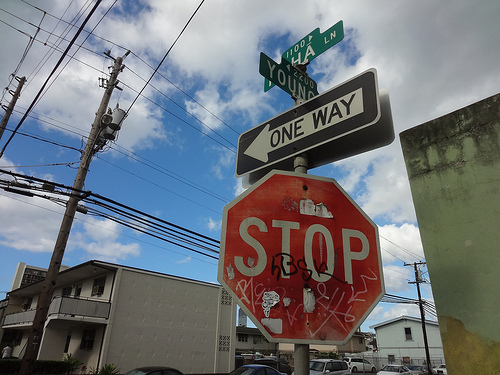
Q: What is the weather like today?
A: It is cloudy.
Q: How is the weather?
A: It is cloudy.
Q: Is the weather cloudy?
A: Yes, it is cloudy.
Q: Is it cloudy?
A: Yes, it is cloudy.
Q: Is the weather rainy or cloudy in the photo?
A: It is cloudy.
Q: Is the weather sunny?
A: No, it is cloudy.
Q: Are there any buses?
A: No, there are no buses.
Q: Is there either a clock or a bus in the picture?
A: No, there are no buses or clocks.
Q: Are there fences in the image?
A: Yes, there is a fence.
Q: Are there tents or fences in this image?
A: Yes, there is a fence.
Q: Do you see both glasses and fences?
A: No, there is a fence but no glasses.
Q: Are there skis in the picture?
A: No, there are no skis.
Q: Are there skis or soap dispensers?
A: No, there are no skis or soap dispensers.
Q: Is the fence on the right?
A: Yes, the fence is on the right of the image.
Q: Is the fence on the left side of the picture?
A: No, the fence is on the right of the image.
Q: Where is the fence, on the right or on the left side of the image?
A: The fence is on the right of the image.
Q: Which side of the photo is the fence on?
A: The fence is on the right of the image.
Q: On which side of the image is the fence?
A: The fence is on the right of the image.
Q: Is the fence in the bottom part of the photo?
A: Yes, the fence is in the bottom of the image.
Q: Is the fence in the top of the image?
A: No, the fence is in the bottom of the image.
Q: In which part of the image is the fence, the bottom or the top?
A: The fence is in the bottom of the image.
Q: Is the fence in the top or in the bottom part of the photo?
A: The fence is in the bottom of the image.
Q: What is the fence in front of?
A: The fence is in front of the building.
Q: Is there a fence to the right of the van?
A: Yes, there is a fence to the right of the van.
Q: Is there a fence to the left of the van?
A: No, the fence is to the right of the van.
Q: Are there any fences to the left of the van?
A: No, the fence is to the right of the van.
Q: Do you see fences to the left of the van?
A: No, the fence is to the right of the van.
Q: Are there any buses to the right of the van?
A: No, there is a fence to the right of the van.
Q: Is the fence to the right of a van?
A: Yes, the fence is to the right of a van.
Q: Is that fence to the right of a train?
A: No, the fence is to the right of a van.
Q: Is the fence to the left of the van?
A: No, the fence is to the right of the van.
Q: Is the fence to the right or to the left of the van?
A: The fence is to the right of the van.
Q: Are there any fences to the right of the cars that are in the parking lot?
A: Yes, there is a fence to the right of the cars.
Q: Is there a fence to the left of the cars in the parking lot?
A: No, the fence is to the right of the cars.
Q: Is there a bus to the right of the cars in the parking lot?
A: No, there is a fence to the right of the cars.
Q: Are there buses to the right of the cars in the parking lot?
A: No, there is a fence to the right of the cars.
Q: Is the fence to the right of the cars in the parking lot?
A: Yes, the fence is to the right of the cars.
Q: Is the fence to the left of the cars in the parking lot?
A: No, the fence is to the right of the cars.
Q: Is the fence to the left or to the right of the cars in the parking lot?
A: The fence is to the right of the cars.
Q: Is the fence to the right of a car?
A: Yes, the fence is to the right of a car.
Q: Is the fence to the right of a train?
A: No, the fence is to the right of a car.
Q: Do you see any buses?
A: No, there are no buses.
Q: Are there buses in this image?
A: No, there are no buses.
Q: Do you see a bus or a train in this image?
A: No, there are no buses or trains.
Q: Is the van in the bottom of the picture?
A: Yes, the van is in the bottom of the image.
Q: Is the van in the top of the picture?
A: No, the van is in the bottom of the image.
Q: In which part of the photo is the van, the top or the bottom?
A: The van is in the bottom of the image.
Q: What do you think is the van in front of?
A: The van is in front of the building.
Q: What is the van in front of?
A: The van is in front of the building.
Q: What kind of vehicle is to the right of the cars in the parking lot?
A: The vehicle is a van.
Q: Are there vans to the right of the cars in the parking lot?
A: Yes, there is a van to the right of the cars.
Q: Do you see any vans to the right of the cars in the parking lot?
A: Yes, there is a van to the right of the cars.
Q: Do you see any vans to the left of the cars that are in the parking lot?
A: No, the van is to the right of the cars.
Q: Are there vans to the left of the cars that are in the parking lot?
A: No, the van is to the right of the cars.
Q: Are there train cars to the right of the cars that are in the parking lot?
A: No, there is a van to the right of the cars.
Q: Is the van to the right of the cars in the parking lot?
A: Yes, the van is to the right of the cars.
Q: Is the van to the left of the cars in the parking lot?
A: No, the van is to the right of the cars.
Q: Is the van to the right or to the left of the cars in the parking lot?
A: The van is to the right of the cars.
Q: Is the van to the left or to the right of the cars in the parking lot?
A: The van is to the right of the cars.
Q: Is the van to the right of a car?
A: Yes, the van is to the right of a car.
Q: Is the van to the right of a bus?
A: No, the van is to the right of a car.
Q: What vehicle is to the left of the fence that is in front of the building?
A: The vehicle is a van.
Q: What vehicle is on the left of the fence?
A: The vehicle is a van.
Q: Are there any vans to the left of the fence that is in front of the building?
A: Yes, there is a van to the left of the fence.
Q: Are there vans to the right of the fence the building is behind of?
A: No, the van is to the left of the fence.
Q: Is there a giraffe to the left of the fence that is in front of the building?
A: No, there is a van to the left of the fence.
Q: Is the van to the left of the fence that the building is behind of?
A: Yes, the van is to the left of the fence.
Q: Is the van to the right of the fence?
A: No, the van is to the left of the fence.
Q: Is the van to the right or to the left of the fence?
A: The van is to the left of the fence.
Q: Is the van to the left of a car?
A: Yes, the van is to the left of a car.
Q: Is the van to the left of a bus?
A: No, the van is to the left of a car.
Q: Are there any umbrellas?
A: No, there are no umbrellas.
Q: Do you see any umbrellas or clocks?
A: No, there are no umbrellas or clocks.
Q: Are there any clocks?
A: No, there are no clocks.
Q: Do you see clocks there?
A: No, there are no clocks.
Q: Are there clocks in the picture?
A: No, there are no clocks.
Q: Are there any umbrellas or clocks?
A: No, there are no clocks or umbrellas.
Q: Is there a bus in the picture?
A: No, there are no buses.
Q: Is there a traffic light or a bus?
A: No, there are no buses or traffic lights.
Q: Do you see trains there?
A: No, there are no trains.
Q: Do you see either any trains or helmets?
A: No, there are no trains or helmets.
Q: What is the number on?
A: The number is on the sign.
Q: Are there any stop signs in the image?
A: Yes, there is a stop sign.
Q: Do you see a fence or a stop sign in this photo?
A: Yes, there is a stop sign.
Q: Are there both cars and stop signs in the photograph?
A: Yes, there are both a stop sign and a car.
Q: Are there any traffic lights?
A: No, there are no traffic lights.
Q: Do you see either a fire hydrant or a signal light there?
A: No, there are no traffic lights or fire hydrants.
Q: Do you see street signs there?
A: Yes, there is a street sign.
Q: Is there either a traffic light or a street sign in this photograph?
A: Yes, there is a street sign.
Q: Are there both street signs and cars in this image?
A: Yes, there are both a street sign and a car.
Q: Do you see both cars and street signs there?
A: Yes, there are both a street sign and a car.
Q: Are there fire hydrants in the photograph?
A: No, there are no fire hydrants.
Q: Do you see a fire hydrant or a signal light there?
A: No, there are no fire hydrants or traffic lights.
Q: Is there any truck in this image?
A: No, there are no trucks.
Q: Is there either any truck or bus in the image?
A: No, there are no trucks or buses.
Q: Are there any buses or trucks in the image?
A: No, there are no trucks or buses.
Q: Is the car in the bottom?
A: Yes, the car is in the bottom of the image.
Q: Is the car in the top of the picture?
A: No, the car is in the bottom of the image.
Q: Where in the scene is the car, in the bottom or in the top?
A: The car is in the bottom of the image.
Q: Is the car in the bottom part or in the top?
A: The car is in the bottom of the image.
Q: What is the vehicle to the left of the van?
A: The vehicle is a car.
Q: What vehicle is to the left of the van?
A: The vehicle is a car.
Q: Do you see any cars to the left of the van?
A: Yes, there is a car to the left of the van.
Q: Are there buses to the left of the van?
A: No, there is a car to the left of the van.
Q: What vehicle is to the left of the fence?
A: The vehicle is a car.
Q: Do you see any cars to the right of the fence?
A: No, the car is to the left of the fence.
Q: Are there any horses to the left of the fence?
A: No, there is a car to the left of the fence.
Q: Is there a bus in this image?
A: No, there are no buses.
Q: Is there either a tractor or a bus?
A: No, there are no buses or tractors.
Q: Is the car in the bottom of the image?
A: Yes, the car is in the bottom of the image.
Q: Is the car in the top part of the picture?
A: No, the car is in the bottom of the image.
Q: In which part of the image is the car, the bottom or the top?
A: The car is in the bottom of the image.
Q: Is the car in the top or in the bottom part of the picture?
A: The car is in the bottom of the image.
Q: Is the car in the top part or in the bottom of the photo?
A: The car is in the bottom of the image.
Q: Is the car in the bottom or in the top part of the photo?
A: The car is in the bottom of the image.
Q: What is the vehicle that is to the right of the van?
A: The vehicle is a car.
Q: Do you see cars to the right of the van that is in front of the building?
A: Yes, there is a car to the right of the van.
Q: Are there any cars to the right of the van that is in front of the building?
A: Yes, there is a car to the right of the van.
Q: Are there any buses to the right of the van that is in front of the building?
A: No, there is a car to the right of the van.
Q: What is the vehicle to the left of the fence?
A: The vehicle is a car.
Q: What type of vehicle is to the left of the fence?
A: The vehicle is a car.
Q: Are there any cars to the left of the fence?
A: Yes, there is a car to the left of the fence.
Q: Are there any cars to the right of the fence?
A: No, the car is to the left of the fence.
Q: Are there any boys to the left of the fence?
A: No, there is a car to the left of the fence.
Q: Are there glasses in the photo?
A: No, there are no glasses.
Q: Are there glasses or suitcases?
A: No, there are no glasses or suitcases.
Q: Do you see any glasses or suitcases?
A: No, there are no glasses or suitcases.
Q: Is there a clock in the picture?
A: No, there are no clocks.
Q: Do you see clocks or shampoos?
A: No, there are no clocks or shampoos.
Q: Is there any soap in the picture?
A: No, there are no soaps.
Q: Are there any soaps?
A: No, there are no soaps.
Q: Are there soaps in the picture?
A: No, there are no soaps.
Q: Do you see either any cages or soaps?
A: No, there are no soaps or cages.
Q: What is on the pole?
A: The wires are on the pole.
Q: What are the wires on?
A: The wires are on the pole.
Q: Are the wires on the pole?
A: Yes, the wires are on the pole.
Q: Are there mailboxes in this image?
A: No, there are no mailboxes.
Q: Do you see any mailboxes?
A: No, there are no mailboxes.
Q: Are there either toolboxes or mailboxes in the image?
A: No, there are no mailboxes or toolboxes.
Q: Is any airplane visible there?
A: No, there are no airplanes.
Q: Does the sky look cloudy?
A: Yes, the sky is cloudy.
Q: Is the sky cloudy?
A: Yes, the sky is cloudy.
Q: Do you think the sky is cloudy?
A: Yes, the sky is cloudy.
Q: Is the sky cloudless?
A: No, the sky is cloudy.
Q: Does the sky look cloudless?
A: No, the sky is cloudy.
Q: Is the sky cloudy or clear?
A: The sky is cloudy.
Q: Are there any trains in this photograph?
A: No, there are no trains.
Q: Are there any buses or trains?
A: No, there are no trains or buses.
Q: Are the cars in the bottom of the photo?
A: Yes, the cars are in the bottom of the image.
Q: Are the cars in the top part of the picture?
A: No, the cars are in the bottom of the image.